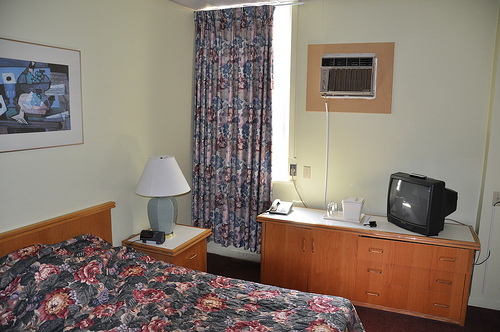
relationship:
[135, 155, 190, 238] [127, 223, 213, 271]
lamp sitting stand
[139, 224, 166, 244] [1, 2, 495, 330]
alarm clock in a hotel room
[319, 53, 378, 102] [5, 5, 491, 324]
ac in a hotel room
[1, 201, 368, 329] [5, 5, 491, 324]
bed in a hotel room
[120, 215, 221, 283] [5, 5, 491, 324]
night stand in a room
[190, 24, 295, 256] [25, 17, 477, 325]
curtain in a hotel room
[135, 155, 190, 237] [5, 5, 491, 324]
lamp in a room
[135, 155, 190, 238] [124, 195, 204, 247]
lamp on a night stand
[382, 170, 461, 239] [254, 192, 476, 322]
tv on a dresser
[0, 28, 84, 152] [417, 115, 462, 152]
painting on wall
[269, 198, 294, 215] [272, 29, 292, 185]
phone by window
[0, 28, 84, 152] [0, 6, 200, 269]
painting on a wall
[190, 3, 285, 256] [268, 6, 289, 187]
curtain on a window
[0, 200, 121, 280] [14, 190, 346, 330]
headboard on a bed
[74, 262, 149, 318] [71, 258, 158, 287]
blanket has flowers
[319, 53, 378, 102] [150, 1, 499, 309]
ac in wall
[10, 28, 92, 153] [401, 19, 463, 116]
painting on wall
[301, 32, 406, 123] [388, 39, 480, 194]
ac fixed to wall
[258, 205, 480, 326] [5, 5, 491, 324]
dresser in room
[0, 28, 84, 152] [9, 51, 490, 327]
painting in room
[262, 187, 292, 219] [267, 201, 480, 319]
phone on dresser